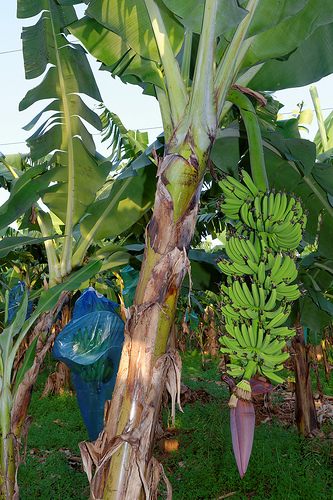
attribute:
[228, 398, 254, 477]
tip — purple, colored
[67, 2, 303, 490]
tree — middle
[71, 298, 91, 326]
plastic bag — blue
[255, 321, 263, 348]
banana — bunch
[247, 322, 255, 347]
banana — bunch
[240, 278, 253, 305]
banana — bunch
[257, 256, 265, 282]
banana — bunch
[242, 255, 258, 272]
banana — bunch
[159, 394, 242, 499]
bushing — green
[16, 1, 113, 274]
leaf — large, tropical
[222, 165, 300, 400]
bananas — prepared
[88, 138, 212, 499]
trunk — peeling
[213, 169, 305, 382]
bananas — green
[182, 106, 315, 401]
banana — green, hanging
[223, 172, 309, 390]
bananas — hanging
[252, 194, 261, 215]
banana — large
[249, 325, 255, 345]
banana — large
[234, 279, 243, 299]
banana — large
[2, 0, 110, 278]
leaf — banana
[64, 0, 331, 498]
tree — banana tree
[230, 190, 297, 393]
banana — green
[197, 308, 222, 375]
trees — thick 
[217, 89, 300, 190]
branch — hanging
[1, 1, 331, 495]
trees — tall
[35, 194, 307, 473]
trees — banana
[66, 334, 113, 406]
plastic — blue